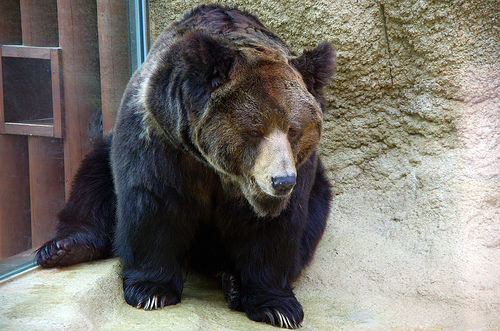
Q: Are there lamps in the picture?
A: No, there are no lamps.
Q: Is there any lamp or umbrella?
A: No, there are no lamps or umbrellas.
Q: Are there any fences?
A: No, there are no fences.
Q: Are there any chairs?
A: No, there are no chairs.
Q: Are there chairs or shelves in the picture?
A: No, there are no chairs or shelves.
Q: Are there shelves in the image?
A: No, there are no shelves.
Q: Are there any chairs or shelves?
A: No, there are no shelves or chairs.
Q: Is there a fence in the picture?
A: No, there are no fences.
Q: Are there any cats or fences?
A: No, there are no fences or cats.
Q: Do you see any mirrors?
A: No, there are no mirrors.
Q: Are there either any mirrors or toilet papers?
A: No, there are no mirrors or toilet papers.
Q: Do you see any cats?
A: No, there are no cats.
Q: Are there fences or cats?
A: No, there are no cats or fences.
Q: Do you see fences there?
A: No, there are no fences.